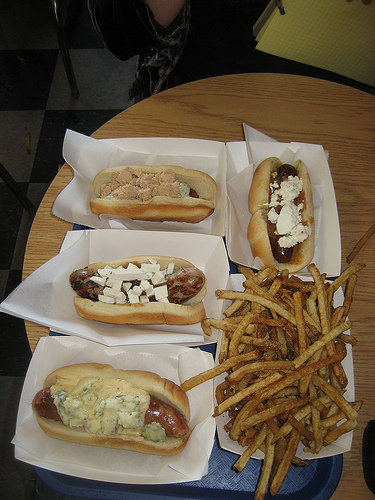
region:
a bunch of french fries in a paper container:
[205, 264, 364, 485]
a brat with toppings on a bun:
[28, 360, 193, 455]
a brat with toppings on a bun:
[65, 255, 211, 324]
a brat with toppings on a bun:
[92, 164, 216, 213]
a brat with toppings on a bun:
[246, 152, 316, 273]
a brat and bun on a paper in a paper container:
[40, 251, 221, 341]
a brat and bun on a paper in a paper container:
[25, 351, 214, 475]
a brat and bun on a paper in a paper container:
[56, 124, 232, 243]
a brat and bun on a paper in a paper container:
[222, 116, 340, 276]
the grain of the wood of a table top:
[205, 77, 308, 118]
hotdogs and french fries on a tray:
[7, 116, 349, 497]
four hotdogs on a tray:
[33, 143, 319, 451]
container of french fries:
[169, 268, 365, 478]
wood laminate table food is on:
[12, 66, 370, 498]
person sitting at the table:
[88, 6, 370, 100]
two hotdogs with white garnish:
[62, 152, 318, 334]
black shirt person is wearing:
[91, 0, 373, 85]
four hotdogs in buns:
[40, 150, 318, 440]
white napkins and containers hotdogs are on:
[8, 110, 340, 473]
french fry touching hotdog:
[170, 352, 256, 385]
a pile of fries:
[181, 259, 374, 499]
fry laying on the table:
[338, 216, 373, 262]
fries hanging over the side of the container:
[224, 451, 312, 494]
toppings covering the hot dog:
[239, 155, 326, 271]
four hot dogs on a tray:
[8, 113, 351, 498]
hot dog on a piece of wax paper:
[7, 334, 214, 485]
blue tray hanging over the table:
[13, 341, 134, 498]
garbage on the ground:
[18, 121, 45, 164]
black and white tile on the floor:
[0, 2, 141, 495]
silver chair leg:
[50, 3, 82, 108]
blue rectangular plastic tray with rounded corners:
[28, 136, 347, 499]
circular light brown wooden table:
[16, 69, 373, 498]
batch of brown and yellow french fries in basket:
[169, 234, 364, 498]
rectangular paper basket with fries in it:
[210, 268, 357, 461]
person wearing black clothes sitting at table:
[81, 0, 373, 107]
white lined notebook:
[248, 0, 373, 91]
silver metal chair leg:
[47, 0, 81, 101]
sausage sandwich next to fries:
[30, 360, 195, 454]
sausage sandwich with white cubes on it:
[67, 253, 210, 329]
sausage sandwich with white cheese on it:
[245, 153, 317, 276]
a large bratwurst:
[55, 245, 224, 321]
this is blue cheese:
[55, 379, 147, 439]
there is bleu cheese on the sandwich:
[23, 363, 220, 455]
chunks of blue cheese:
[48, 381, 184, 439]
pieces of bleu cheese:
[51, 382, 174, 450]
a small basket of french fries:
[225, 268, 373, 468]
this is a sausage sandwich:
[62, 227, 227, 327]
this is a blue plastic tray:
[19, 448, 358, 498]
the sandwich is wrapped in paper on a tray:
[62, 130, 229, 236]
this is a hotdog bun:
[78, 299, 211, 324]